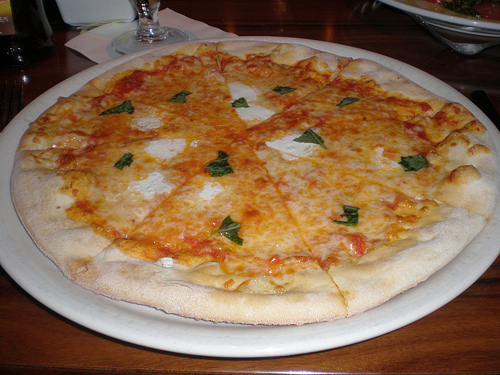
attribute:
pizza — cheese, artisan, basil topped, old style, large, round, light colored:
[6, 31, 495, 336]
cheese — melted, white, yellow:
[98, 66, 425, 258]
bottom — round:
[111, 29, 191, 58]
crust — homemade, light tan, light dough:
[17, 31, 493, 335]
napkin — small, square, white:
[65, 5, 227, 67]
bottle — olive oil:
[3, 2, 58, 72]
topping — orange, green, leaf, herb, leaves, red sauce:
[61, 50, 459, 258]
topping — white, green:
[130, 86, 325, 219]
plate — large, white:
[2, 35, 500, 369]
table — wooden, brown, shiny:
[6, 6, 496, 373]